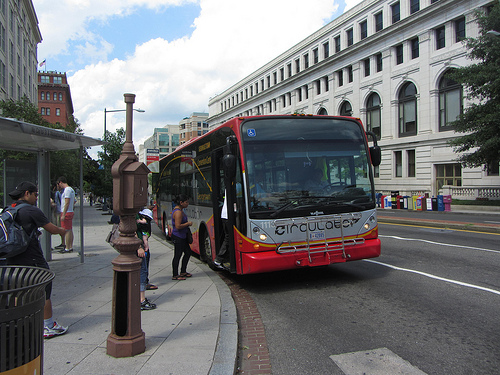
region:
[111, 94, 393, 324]
a public bus stopped at a corner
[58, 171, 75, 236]
a man wearing red shorts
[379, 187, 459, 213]
a row of newspaper mechines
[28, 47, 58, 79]
a flag on a flag pole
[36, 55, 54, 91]
a flag and pole on top of a building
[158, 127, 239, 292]
a woman getting on a bus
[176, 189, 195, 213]
a woman with black hair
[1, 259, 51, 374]
a metal garbage can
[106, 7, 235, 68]
white clouds in a blue sky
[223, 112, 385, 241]
a windshield on a bus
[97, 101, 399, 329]
Red bus parked by the sidewalk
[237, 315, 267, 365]
Brick design by the sidewalk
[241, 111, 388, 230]
Front window on the bus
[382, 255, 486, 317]
white paint on the road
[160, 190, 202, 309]
Woman waiting to get on the bus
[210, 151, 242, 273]
People getting in to the bus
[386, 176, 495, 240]
news paper boxes beside the road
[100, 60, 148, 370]
Pole standing by the road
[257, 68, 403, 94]
Windows on top of the building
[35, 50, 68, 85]
Flag on top of building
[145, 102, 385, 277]
a red and gray bus.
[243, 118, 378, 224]
a large windshield on a bus..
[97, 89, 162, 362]
a metal post on a sidewalk.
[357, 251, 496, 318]
a white line on a road.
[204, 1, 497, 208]
a white multi story building.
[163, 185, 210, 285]
a woman waiting outside of a bus.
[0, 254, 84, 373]
a trash can on a corner.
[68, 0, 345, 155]
a large white cloud.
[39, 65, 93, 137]
a multi story brick building.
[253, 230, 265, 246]
a headlight on a bus.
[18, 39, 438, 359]
a bus stopped at a bus stop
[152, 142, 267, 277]
a woman getting on a city bus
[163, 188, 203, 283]
a woman wearing a blue blouse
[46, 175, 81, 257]
a man wearing a white t-shirt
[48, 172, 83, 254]
a man wearing red shorts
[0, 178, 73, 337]
a man wearing a black baseball cap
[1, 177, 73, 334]
a man wearing a back pack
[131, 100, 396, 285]
a red and silver city bus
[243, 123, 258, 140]
a handicap symbol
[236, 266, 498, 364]
a city street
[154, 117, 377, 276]
red city bus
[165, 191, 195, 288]
woman waiting to get on bus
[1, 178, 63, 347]
man with a back pack on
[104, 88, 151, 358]
old timey police telephone box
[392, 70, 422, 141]
rounded glass window of stone building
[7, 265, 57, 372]
trash can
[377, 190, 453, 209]
assortment of various newspapers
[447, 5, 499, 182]
green pine tree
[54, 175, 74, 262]
man in red shorts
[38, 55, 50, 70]
the american flag